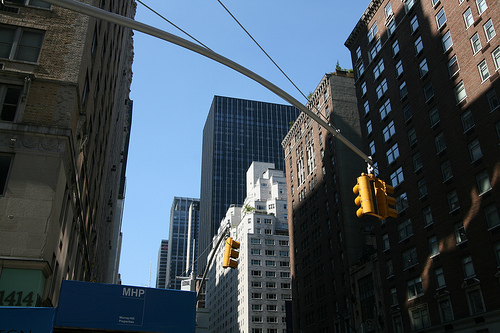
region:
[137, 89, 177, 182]
this is the sky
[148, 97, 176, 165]
the sky is blue in color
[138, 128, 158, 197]
the sky is clear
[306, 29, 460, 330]
these are two buildings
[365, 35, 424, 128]
this building has several windows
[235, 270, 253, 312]
the building is white in color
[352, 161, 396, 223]
this is a traffic light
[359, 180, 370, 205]
the casing is white in color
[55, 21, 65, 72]
the building is made of stone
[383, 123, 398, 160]
the windows are closed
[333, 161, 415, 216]
The stoplight is yellow.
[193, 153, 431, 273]
There are three stoplights in the picture.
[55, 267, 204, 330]
The box is blue.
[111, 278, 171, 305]
"MHP" is written on the box.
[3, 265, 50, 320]
Number on the side of a building.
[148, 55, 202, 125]
The sky is blue.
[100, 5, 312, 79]
The stoplight pole is silver.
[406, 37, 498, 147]
The building is dark brown.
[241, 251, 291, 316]
The building is white.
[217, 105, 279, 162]
The building has a lot of windows.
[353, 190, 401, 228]
part of a traffic light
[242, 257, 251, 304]
edge of a building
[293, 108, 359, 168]
part of a metal post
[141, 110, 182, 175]
part of a blue sky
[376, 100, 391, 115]
a window on the building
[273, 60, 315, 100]
part of a string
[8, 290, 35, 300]
part of a number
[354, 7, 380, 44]
top of a building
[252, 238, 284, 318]
windows on a building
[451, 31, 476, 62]
brown part of the building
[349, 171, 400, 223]
A yellow traffic light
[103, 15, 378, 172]
A metal pole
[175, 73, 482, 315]
A row of tall buildings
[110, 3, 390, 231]
A traffic light hanging on a pole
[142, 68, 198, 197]
A clear blue sky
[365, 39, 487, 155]
Windows on a building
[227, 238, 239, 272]
The lights on a traffic light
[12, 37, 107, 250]
The corner of a brick building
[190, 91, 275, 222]
A tall gray building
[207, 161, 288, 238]
The top of a white building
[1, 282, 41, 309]
numbers on city building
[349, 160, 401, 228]
hanging yellow street light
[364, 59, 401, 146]
reflection on building windows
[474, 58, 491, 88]
window with blind partially open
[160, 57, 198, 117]
clear blue daytime sky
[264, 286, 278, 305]
window with no curtain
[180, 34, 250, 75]
metal pole for light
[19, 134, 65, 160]
ornamental design on building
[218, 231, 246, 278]
side view of street light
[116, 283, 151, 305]
three white letters on blue background